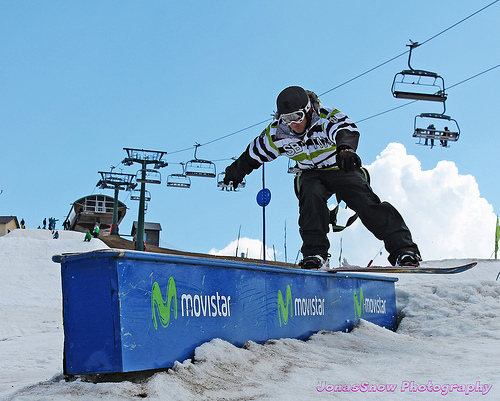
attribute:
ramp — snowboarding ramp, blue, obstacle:
[52, 244, 404, 377]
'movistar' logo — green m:
[146, 272, 183, 334]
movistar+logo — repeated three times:
[142, 269, 236, 336]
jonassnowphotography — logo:
[319, 379, 492, 396]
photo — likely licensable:
[2, 0, 498, 399]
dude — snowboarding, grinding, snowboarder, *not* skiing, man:
[202, 73, 481, 278]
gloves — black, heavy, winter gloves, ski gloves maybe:
[218, 148, 363, 194]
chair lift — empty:
[382, 36, 453, 108]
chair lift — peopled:
[405, 85, 476, 153]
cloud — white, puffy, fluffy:
[318, 136, 498, 260]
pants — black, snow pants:
[293, 168, 424, 260]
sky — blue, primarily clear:
[2, 1, 499, 256]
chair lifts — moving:
[126, 6, 499, 213]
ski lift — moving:
[52, 1, 499, 234]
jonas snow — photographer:
[313, 377, 398, 396]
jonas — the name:
[312, 377, 357, 397]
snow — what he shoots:
[360, 378, 398, 396]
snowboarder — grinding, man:
[220, 83, 428, 264]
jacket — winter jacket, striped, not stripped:
[243, 105, 369, 172]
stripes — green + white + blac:
[243, 111, 362, 191]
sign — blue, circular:
[254, 183, 276, 209]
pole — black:
[263, 152, 267, 263]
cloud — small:
[208, 230, 284, 265]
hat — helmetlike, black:
[270, 77, 313, 117]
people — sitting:
[415, 121, 461, 147]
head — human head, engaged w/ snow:
[272, 82, 317, 142]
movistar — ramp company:
[269, 283, 332, 329]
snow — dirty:
[0, 313, 396, 401]